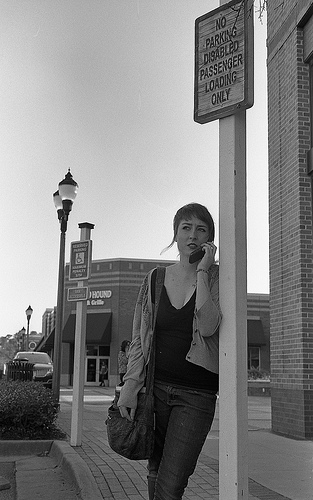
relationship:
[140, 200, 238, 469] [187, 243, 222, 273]
woman on phone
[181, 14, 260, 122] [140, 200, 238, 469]
sign above woman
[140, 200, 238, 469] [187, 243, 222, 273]
woman holding phone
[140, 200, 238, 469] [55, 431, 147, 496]
woman on sidewalk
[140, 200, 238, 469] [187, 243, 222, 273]
woman using phone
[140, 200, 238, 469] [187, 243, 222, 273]
woman on her phone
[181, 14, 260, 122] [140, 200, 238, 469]
sign near woman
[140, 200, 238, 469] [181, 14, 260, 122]
woman below sign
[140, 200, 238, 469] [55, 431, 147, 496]
woman standing on sidewalk